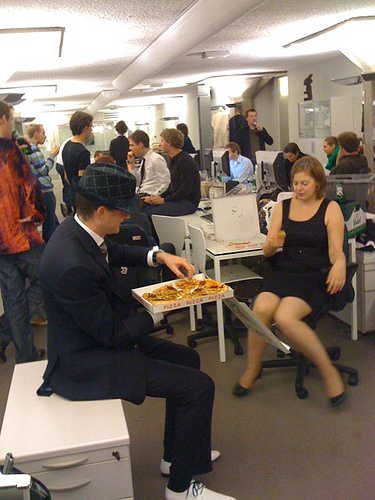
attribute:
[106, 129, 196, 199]
men — in the picture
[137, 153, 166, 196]
dress shirt — white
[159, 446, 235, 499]
shoes — white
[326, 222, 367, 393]
chair — rolling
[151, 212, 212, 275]
chairs — white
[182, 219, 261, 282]
chairs — white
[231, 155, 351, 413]
woman — sitting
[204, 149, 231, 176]
computer — in the picture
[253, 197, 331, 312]
dress — black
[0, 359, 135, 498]
trunk — white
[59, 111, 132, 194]
man — eating, walking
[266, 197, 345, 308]
dress — sleeveless, black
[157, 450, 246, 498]
shoes — white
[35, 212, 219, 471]
suit — black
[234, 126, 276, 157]
coat — black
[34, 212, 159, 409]
jacket — black  